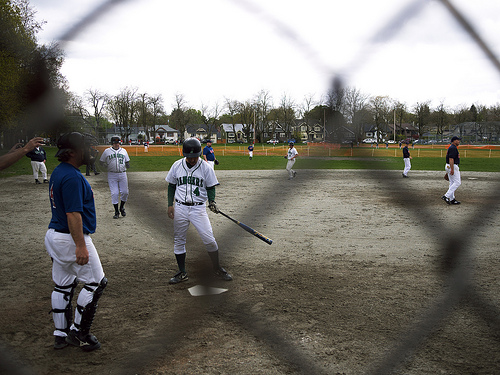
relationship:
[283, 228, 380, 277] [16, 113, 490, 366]
dirt on baseball field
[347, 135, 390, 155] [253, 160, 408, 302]
fence around field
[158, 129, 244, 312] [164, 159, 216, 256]
man in jersey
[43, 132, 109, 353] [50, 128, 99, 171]
catcher wearing equipment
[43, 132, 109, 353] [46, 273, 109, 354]
catcher wearing equipment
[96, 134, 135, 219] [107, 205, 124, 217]
runner on base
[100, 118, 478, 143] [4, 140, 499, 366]
houses behind baseball field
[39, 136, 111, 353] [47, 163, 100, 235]
catcher wearing blue shirt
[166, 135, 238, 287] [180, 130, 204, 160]
man wearing helmet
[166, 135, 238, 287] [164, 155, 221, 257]
man wearing jersey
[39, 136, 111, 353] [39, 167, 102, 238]
catcher wears blue shirt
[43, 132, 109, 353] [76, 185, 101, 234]
catcher has belly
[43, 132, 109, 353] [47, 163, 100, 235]
catcher in blue shirt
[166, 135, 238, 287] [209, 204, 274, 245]
man up to baseball bat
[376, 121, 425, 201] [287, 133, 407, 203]
player walking to outfield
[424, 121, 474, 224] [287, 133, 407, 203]
player walking to outfield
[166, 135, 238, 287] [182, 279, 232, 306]
man standing at home plate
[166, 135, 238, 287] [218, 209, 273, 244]
man holding bat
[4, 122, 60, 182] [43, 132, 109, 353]
arm reaching for catcher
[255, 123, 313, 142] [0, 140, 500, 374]
houses across from baseball field